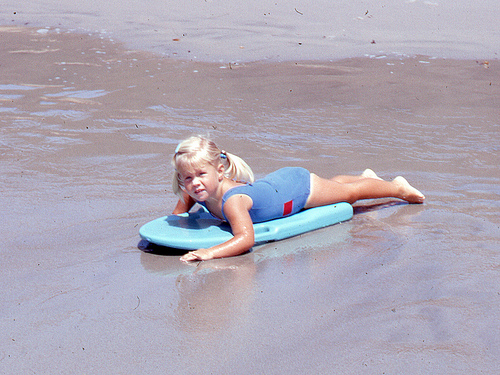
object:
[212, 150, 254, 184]
pigtails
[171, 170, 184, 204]
pigtails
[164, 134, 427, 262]
baby's skin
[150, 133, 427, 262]
girl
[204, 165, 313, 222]
swimsuit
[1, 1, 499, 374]
water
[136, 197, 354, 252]
board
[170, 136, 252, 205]
girl's hair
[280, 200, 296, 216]
red stripe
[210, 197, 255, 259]
girl's arm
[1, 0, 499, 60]
sand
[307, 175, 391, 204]
girl's legs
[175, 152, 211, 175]
bangs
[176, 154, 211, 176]
forehead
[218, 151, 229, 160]
barrette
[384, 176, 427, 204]
feet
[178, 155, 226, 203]
girl's face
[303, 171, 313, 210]
line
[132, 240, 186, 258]
shadow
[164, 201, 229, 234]
reflection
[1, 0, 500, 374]
scene